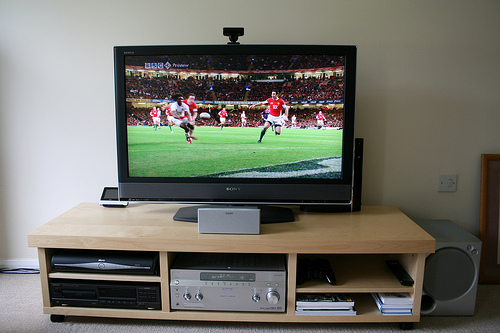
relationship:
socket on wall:
[426, 166, 498, 217] [378, 41, 498, 193]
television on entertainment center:
[113, 45, 360, 222] [26, 201, 435, 321]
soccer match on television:
[123, 55, 348, 176] [111, 24, 364, 222]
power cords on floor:
[0, 265, 43, 275] [0, 272, 35, 331]